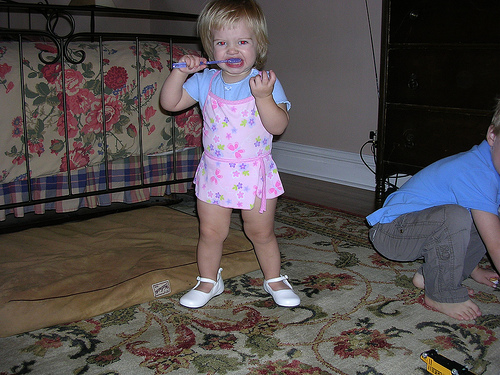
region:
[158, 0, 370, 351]
The girl is standing on a rug.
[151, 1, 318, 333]
The girl is wearing shoes.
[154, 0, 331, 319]
The girl's shoes are white.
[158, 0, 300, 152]
The girl is holding a toothbrush.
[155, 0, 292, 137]
The toothbrush is purple.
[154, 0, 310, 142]
The girl is brushing her teeth.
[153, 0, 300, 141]
The girl is wearing a shirt.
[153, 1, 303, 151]
The girl's shirt is blue.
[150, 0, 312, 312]
The girl is wearing a dress over her shirt.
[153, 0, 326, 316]
The girl's dress is pink.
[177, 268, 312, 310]
white buckle shoes worn by a little girl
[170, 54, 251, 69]
purple toothbrush held by a little girl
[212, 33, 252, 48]
red eye glare from the camera's flash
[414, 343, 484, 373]
a yellow toy bus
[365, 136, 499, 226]
a blue short sleeved shirt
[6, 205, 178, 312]
a brown dog bed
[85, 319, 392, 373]
flower patterned area rug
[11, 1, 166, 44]
metal bed frame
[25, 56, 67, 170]
flower printed blanket on a bed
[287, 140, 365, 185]
white molding on the wall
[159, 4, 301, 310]
young girl brushing her teeth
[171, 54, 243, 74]
toothbrush in a girl's hand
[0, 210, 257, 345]
a light brown pillow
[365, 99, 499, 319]
a young boy on carpet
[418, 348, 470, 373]
a yellow and black toy car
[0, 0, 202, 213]
metal frame on a bed's end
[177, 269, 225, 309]
a girl's white shoe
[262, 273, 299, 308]
a girl's white shoe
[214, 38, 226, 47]
eye of a girl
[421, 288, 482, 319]
a boy's foot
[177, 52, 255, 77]
A blue toothbrush in the child's mouth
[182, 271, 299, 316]
White slippers on the kid's feet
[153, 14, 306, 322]
The little girl is brushing her teeth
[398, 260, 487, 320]
The boy is barefoot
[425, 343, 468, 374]
An overturned yellow toy truck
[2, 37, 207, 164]
A floral design on the blanket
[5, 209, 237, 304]
A thin brown mat behind the girl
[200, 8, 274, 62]
The girl has short blonde hair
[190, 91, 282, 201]
The girl wears a pink dress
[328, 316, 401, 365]
A red flower design on the rug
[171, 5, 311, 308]
child brushing her teeth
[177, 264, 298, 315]
white shoes of girl brushing teeth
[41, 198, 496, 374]
area rug children are standing on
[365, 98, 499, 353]
boy crouched on area rug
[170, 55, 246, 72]
toothbrush child is holding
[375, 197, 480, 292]
gray pants of little boy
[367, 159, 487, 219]
blue shirt of little boy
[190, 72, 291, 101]
light blue shirt of girl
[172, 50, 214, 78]
hand holding purple toothbrush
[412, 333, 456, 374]
yellow car toy on rug